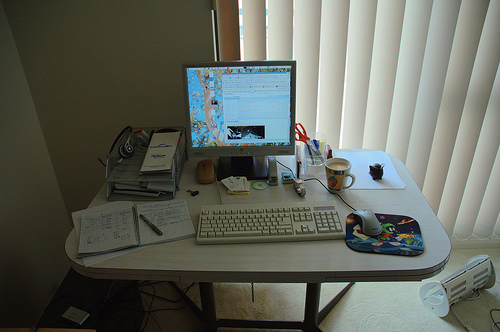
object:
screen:
[186, 64, 293, 150]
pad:
[347, 212, 428, 257]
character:
[379, 219, 398, 250]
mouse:
[352, 207, 382, 236]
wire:
[274, 160, 360, 213]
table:
[63, 148, 453, 282]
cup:
[325, 157, 353, 194]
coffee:
[329, 161, 346, 169]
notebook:
[77, 199, 199, 258]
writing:
[144, 207, 186, 228]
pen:
[141, 212, 164, 237]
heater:
[419, 255, 500, 315]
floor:
[100, 247, 500, 332]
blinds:
[233, 0, 500, 242]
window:
[208, 3, 500, 240]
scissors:
[292, 122, 321, 164]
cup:
[303, 131, 327, 166]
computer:
[175, 59, 300, 186]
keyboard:
[197, 199, 346, 247]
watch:
[292, 177, 306, 197]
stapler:
[267, 155, 280, 188]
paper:
[329, 149, 408, 189]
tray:
[110, 121, 180, 202]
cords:
[67, 281, 195, 329]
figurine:
[367, 162, 387, 181]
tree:
[188, 68, 225, 146]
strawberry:
[328, 175, 338, 188]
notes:
[86, 214, 117, 232]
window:
[223, 73, 289, 141]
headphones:
[119, 133, 137, 159]